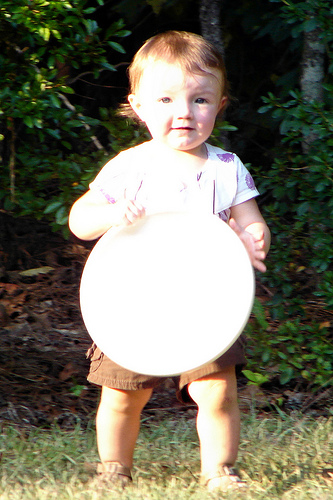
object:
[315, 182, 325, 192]
leaves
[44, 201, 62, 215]
leaves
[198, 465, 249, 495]
foot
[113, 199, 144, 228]
hand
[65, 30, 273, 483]
baby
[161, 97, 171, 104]
eye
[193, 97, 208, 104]
eye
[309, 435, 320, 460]
grass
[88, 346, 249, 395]
baby shorts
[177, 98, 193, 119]
nose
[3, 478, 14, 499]
grass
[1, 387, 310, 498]
ground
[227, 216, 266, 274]
hand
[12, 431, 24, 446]
grass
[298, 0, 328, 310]
tree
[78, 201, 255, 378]
frisbee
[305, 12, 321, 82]
trunk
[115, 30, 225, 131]
hair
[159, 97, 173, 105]
eyes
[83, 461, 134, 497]
sandal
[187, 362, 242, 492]
leg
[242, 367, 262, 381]
leaves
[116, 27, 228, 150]
head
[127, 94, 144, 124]
ear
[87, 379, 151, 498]
leg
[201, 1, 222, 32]
woods